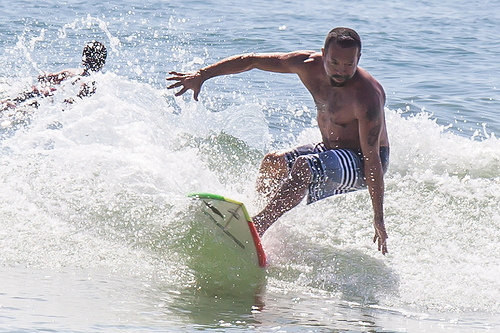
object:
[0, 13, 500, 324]
wave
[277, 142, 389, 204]
shorts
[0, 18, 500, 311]
splash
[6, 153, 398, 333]
reflection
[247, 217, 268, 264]
rim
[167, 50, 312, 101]
arm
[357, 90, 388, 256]
arm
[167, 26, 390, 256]
man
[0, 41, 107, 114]
man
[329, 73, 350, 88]
moustache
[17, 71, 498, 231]
cap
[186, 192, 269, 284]
surfboard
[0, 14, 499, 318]
foam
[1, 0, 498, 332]
water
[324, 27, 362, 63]
hair